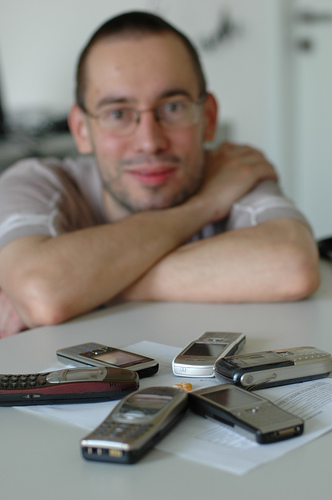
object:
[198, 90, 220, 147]
ear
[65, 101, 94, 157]
ear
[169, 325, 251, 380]
cellphone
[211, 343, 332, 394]
flipphone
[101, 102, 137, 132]
eye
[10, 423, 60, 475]
table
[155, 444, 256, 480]
paper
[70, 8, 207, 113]
hair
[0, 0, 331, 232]
background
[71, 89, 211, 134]
eye lasses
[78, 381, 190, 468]
cell phone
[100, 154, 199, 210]
beard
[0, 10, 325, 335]
man camera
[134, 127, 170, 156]
nose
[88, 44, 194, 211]
face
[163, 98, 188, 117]
eye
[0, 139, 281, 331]
arms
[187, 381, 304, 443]
handset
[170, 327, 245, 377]
handset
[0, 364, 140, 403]
handset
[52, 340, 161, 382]
handset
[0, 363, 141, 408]
camera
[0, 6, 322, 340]
man